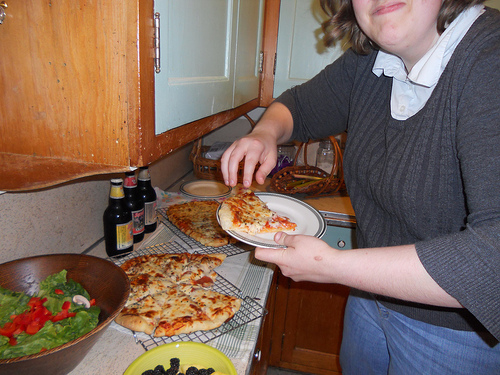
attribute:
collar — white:
[358, 40, 473, 107]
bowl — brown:
[2, 247, 136, 374]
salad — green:
[5, 274, 93, 366]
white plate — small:
[234, 177, 330, 257]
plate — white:
[222, 182, 337, 258]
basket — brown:
[0, 242, 142, 370]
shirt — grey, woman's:
[443, 238, 482, 280]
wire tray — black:
[101, 238, 267, 359]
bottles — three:
[100, 160, 159, 258]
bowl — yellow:
[121, 342, 240, 372]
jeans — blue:
[340, 289, 463, 373]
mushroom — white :
[53, 287, 110, 337]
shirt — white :
[359, 6, 495, 117]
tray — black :
[82, 230, 274, 373]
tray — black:
[97, 232, 274, 359]